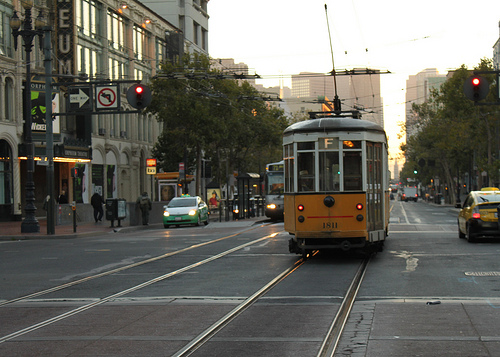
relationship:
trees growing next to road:
[402, 57, 498, 209] [13, 201, 498, 355]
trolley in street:
[273, 106, 403, 268] [0, 178, 495, 350]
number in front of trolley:
[319, 220, 327, 230] [281, 107, 388, 254]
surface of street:
[297, 266, 340, 295] [21, 239, 498, 344]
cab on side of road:
[159, 187, 210, 237] [0, 201, 498, 355]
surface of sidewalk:
[75, 221, 95, 231] [3, 221, 159, 236]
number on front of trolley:
[316, 217, 350, 232] [282, 3, 389, 261]